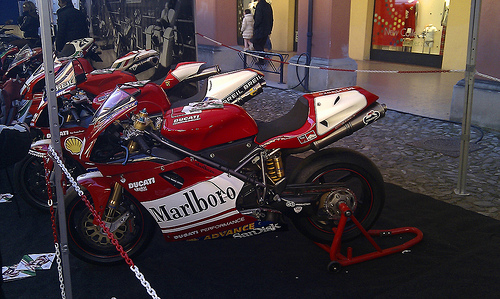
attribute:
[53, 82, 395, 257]
motorcycle — parked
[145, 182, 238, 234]
marlboro logo — black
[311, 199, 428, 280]
bike stand — red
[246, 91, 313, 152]
seat — black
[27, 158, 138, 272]
chain — red, metal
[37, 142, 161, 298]
chain — white, red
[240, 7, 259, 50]
person — walking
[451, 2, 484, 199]
pole — metal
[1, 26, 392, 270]
motorcycles — lined up, red, parked, ducati, white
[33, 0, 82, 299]
pole — metal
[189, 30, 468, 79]
chain — red, white, metal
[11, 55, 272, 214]
motorcycle — parked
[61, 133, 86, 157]
shell logo — yellow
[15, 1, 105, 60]
people — walking, standing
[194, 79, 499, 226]
path — cobblestone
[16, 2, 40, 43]
person — standing